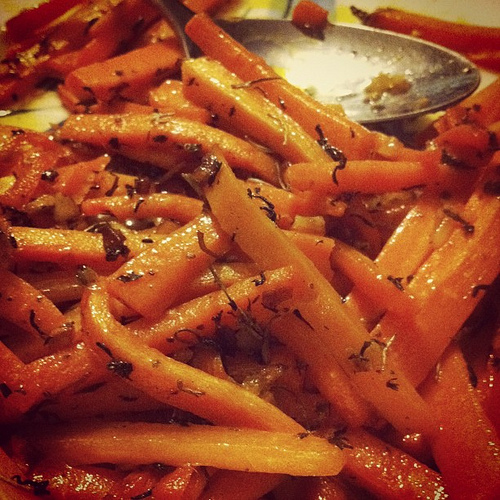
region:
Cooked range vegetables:
[7, 2, 499, 492]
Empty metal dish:
[188, 10, 490, 126]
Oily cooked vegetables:
[8, 3, 493, 489]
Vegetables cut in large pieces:
[7, 1, 490, 485]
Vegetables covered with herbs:
[1, 4, 494, 494]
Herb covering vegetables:
[304, 125, 353, 183]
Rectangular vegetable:
[35, 412, 360, 477]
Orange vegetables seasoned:
[8, 4, 494, 486]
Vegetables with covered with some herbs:
[10, 5, 494, 489]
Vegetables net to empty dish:
[11, 5, 492, 495]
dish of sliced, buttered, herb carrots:
[2, 0, 494, 498]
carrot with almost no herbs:
[39, 419, 346, 476]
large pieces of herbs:
[175, 264, 277, 361]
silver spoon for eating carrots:
[152, 0, 482, 122]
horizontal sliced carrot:
[2, 225, 165, 263]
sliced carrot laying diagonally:
[195, 147, 433, 435]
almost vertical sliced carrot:
[415, 340, 497, 497]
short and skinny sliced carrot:
[287, 161, 434, 190]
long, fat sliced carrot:
[366, 189, 498, 386]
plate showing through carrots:
[1, 2, 498, 132]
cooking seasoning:
[303, 117, 373, 201]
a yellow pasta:
[93, 279, 323, 451]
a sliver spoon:
[259, 10, 498, 130]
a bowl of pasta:
[63, 88, 340, 400]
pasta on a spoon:
[253, 9, 493, 199]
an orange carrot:
[70, 59, 178, 104]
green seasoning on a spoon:
[350, 64, 438, 113]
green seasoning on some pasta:
[349, 330, 409, 400]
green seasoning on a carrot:
[382, 245, 427, 351]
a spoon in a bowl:
[104, 7, 491, 219]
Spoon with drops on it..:
[226, 19, 480, 140]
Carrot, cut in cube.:
[288, 0, 336, 40]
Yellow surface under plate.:
[8, 86, 72, 147]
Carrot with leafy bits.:
[65, 111, 275, 186]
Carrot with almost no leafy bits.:
[71, 426, 346, 480]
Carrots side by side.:
[182, 70, 402, 165]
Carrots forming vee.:
[46, 281, 323, 497]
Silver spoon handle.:
[164, 3, 217, 69]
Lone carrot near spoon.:
[359, 6, 497, 113]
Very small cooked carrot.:
[340, 242, 416, 319]